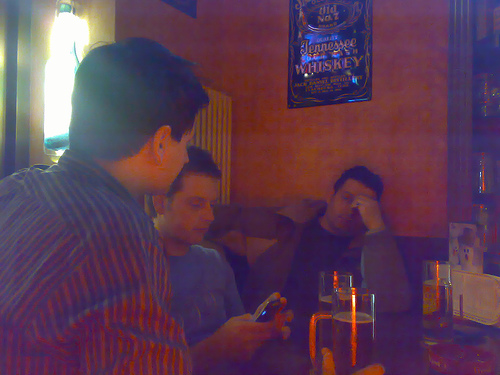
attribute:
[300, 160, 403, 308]
man — leaning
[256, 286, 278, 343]
cellphone — black, plastic, small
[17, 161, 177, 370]
shirt — striped, blue, dress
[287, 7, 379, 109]
sign — whiskey, metal, jack daniels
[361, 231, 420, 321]
coat — brown, gray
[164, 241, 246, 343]
tshirt — light, blue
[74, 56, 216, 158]
hair — short, brown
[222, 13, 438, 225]
wallpaper — orange, brown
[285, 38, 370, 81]
jack daniels — whiskey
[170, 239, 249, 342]
shirt — blue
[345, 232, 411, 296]
jacket — grey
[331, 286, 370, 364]
mug — beer, glass, full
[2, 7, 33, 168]
frame — wood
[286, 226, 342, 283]
shirt — black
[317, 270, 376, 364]
glass — full, clear